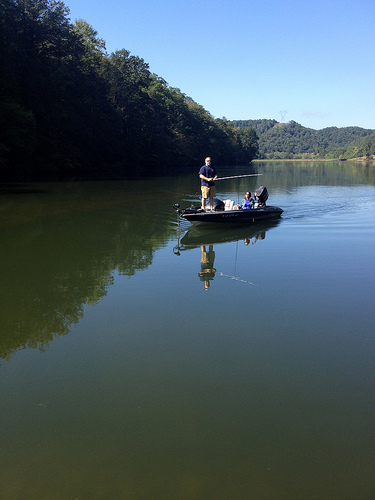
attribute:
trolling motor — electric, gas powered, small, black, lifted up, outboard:
[253, 184, 269, 203]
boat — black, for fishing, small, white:
[180, 200, 284, 221]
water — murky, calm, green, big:
[0, 159, 372, 500]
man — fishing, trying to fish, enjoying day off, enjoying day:
[199, 155, 216, 213]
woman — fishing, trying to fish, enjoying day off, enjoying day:
[241, 191, 255, 210]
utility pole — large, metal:
[277, 107, 289, 124]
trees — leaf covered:
[1, 1, 258, 172]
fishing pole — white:
[214, 172, 263, 182]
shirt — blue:
[198, 165, 217, 186]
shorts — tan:
[200, 185, 215, 199]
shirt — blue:
[241, 200, 254, 208]